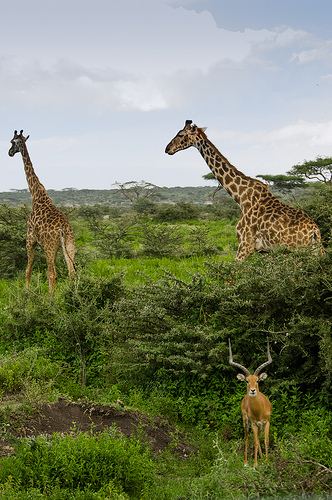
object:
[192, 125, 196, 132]
horns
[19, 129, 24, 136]
horns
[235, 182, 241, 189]
tan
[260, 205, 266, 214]
brown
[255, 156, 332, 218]
trees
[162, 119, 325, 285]
animal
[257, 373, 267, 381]
ear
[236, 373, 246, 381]
ear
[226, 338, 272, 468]
animal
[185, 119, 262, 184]
neck hair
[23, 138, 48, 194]
neck hair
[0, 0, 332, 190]
sky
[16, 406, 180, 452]
dirt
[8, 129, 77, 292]
animal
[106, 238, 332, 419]
greenery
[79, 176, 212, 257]
greenery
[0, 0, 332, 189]
cloud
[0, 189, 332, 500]
grass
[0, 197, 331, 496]
ground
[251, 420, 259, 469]
legs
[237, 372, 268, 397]
head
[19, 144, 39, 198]
neck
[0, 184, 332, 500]
land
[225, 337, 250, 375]
antler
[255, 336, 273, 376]
antler